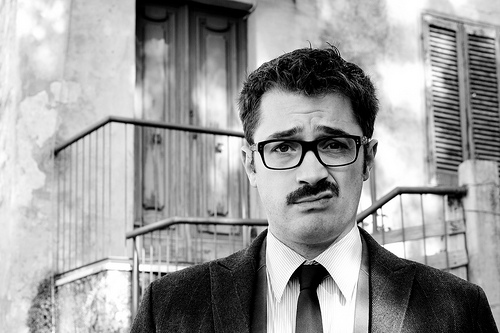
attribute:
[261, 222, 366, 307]
collar — white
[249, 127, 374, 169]
eyeglasses — black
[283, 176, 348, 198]
hair — black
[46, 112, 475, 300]
railings — metal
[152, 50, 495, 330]
he — dissapointed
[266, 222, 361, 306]
collar — down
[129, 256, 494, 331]
coat — black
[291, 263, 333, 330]
tie — black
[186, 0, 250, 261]
door — wooden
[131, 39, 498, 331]
man — wearing, posing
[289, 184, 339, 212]
mouth — lifted up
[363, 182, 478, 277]
railing — along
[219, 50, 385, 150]
hair — dark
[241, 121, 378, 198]
glasses — black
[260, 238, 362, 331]
shirt. — white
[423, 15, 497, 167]
shutters — wooden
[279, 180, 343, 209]
mustache — black